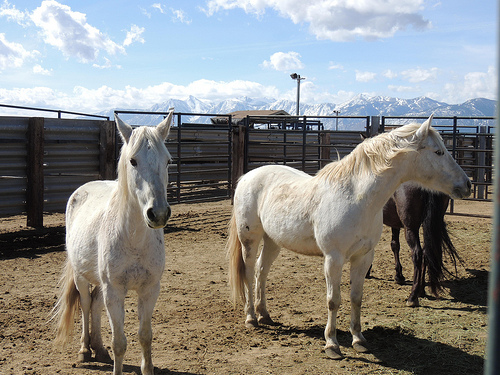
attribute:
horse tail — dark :
[421, 190, 465, 299]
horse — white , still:
[58, 108, 179, 373]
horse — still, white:
[224, 104, 468, 360]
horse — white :
[232, 115, 475, 347]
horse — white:
[57, 111, 207, 365]